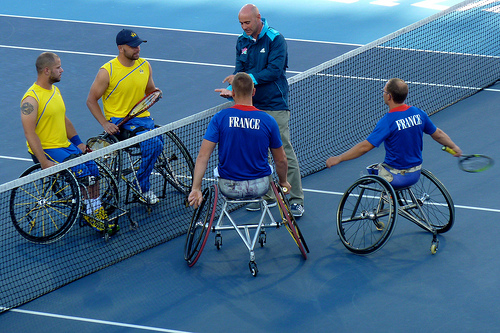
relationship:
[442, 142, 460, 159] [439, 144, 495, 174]
handle of racket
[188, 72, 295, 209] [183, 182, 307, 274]
man in wheelchair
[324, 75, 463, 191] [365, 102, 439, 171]
man in blue shirt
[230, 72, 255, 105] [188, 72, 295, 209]
head of man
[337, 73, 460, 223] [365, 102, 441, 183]
man wearing blue shirt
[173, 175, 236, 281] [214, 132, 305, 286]
tire on wheel chair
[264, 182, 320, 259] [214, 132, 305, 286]
tire on wheel chair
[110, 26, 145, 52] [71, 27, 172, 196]
hat on man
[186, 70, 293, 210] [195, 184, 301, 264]
man sitting in wheel chair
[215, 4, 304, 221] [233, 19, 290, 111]
man wearing a jacket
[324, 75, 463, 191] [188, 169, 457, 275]
man on wheel chairs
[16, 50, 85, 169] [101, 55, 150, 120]
fellow wearing shirt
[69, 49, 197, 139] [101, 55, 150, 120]
fellow wearing shirt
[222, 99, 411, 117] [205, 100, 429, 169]
trim on shirts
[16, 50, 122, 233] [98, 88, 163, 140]
fellow holding racket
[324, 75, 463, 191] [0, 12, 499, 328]
man at court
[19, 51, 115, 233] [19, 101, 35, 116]
man has a tattoo